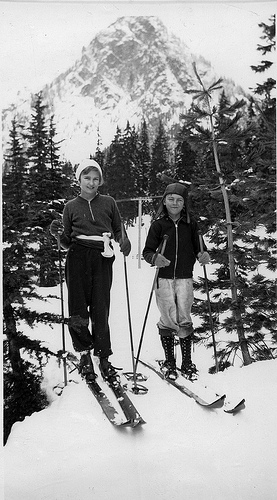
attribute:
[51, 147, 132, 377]
boy — Young 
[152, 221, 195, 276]
coat — black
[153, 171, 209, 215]
hat — black 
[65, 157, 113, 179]
hat — white 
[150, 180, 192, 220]
cap — dark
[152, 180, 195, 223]
cap — black 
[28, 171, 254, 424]
skis — dark 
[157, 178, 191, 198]
hat — brown 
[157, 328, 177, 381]
boot — long, black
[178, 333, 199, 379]
boot — black, long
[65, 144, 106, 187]
hat — white 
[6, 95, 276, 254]
evergreen trees — evergreen 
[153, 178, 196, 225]
black hat — black 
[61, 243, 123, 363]
pants — white 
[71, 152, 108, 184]
cap — white